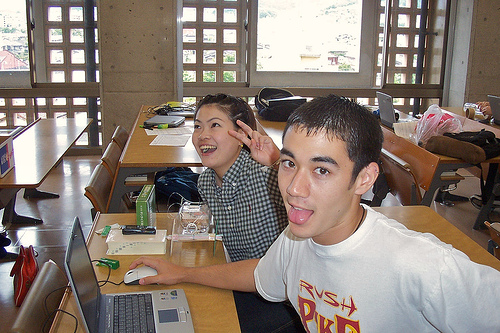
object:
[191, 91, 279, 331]
girl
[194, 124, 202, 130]
eye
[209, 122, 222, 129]
eye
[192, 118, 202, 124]
eyebrow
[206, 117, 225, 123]
eyebrow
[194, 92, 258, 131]
hair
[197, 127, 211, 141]
nose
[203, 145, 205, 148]
teeth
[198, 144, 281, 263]
shirt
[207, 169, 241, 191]
collar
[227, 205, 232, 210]
button